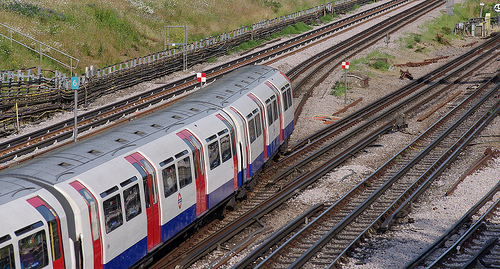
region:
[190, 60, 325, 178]
The train car to the front.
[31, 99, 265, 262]
The train car in the middle.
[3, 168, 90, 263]
The last train car.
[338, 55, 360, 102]
The red and white sign.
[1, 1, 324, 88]
The grassy area.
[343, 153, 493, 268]
The gravel between the tracks.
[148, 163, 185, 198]
square window on train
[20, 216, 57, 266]
square window on train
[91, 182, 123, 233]
square window on train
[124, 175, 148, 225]
square window on train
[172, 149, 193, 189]
square window on train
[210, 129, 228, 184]
square window on train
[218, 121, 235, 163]
square window on train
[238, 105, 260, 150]
square window on train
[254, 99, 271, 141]
square window on train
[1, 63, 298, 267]
Silver train on the tracks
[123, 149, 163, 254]
Red door on side of train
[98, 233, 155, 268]
Blue stripe on bottom of train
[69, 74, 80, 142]
Sign on side of train tracks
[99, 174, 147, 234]
Windows on side of train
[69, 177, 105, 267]
Long window on side of train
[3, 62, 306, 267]
Passenger train driving on tracks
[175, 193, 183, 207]
Logo on side of train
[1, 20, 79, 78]
Metal railing near tracks on hillside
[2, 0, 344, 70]
Grass growing on hill behind tracks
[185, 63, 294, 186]
a silver red and blue passenger train car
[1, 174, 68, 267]
a silver red and blue passenger train car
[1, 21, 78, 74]
a metal hand rail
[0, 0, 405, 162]
a set of train tracks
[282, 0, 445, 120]
a set of train tracks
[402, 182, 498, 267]
a set of train tracks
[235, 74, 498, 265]
a set of train tracks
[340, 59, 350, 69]
a red and white train sign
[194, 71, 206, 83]
a red and white train sign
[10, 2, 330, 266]
this is a train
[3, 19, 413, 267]
train on the tracks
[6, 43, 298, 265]
this is a passenger train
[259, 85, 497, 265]
multiple train track sets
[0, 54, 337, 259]
the train is white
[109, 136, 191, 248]
red trim on the train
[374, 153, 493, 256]
rocks on the tracks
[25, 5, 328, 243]
multiple windows on train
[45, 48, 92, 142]
blue sign on a pole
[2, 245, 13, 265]
glass window on train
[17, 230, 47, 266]
glass window on train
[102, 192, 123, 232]
glass window on train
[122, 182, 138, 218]
glass window on train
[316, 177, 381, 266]
train tracks beside the train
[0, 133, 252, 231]
train on the tracks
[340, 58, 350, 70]
red and white checkerd sign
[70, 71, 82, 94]
green and white sign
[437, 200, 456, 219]
gravel in between the tracks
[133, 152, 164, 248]
doors on the train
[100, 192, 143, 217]
windows on the train